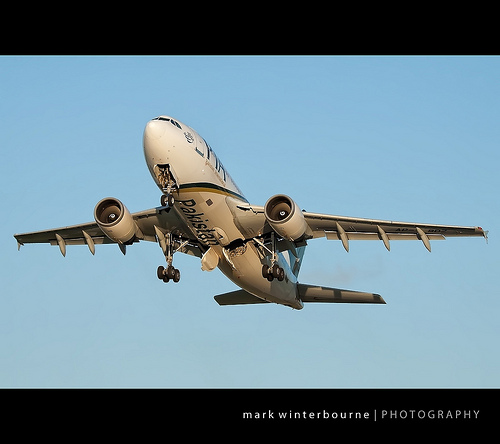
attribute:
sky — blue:
[264, 62, 480, 171]